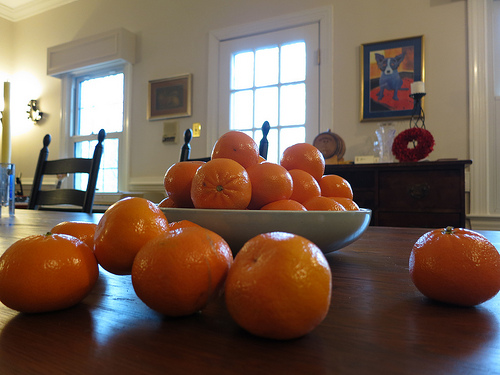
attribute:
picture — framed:
[355, 30, 427, 124]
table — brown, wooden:
[1, 198, 497, 373]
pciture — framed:
[372, 54, 408, 107]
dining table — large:
[1, 205, 498, 373]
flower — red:
[385, 126, 437, 166]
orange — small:
[3, 224, 109, 330]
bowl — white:
[164, 205, 370, 255]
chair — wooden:
[21, 114, 108, 235]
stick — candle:
[394, 64, 444, 157]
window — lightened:
[65, 67, 132, 196]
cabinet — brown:
[308, 151, 476, 232]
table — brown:
[15, 209, 484, 364]